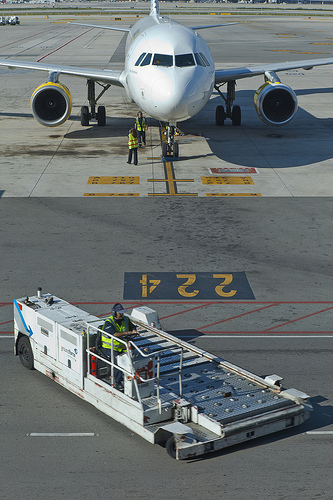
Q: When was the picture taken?
A: Daytime.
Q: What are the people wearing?
A: Headphones.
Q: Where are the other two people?
A: Under the plane.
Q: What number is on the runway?
A: Two hundred twenty-four.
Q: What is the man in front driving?
A: Ground support vehicle.